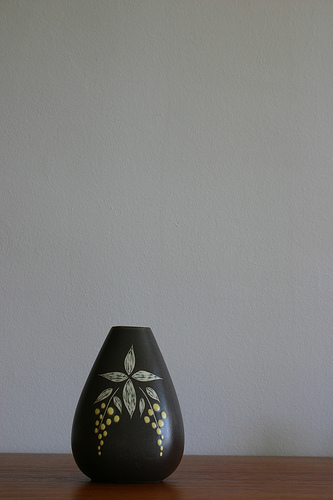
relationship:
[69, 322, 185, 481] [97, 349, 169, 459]
jar has design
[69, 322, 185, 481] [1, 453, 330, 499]
jar on table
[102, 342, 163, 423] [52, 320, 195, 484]
flowers on vase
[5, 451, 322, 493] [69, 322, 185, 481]
furniture under jar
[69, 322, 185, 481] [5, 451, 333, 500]
jar on furniture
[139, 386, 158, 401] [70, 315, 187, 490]
petal on vase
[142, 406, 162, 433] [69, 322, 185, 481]
dots on jar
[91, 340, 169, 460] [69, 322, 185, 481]
plant painted on jar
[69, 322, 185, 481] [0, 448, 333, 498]
jar on table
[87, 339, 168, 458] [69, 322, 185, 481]
leaves painted on jar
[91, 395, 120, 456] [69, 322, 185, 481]
dots painted on jar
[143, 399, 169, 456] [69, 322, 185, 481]
dots painted on jar